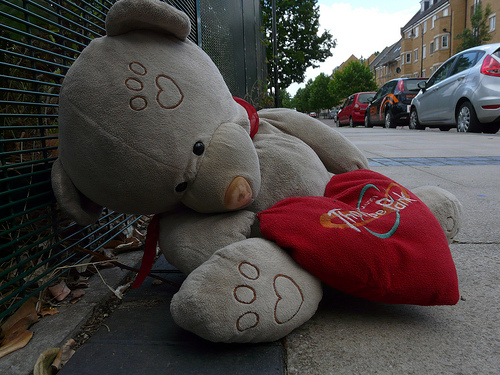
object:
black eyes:
[176, 139, 207, 195]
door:
[3, 0, 145, 265]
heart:
[257, 168, 462, 305]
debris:
[0, 205, 150, 353]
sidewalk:
[0, 127, 499, 374]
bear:
[50, 0, 462, 342]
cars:
[332, 42, 499, 133]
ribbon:
[231, 93, 260, 139]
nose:
[222, 175, 253, 210]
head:
[49, 1, 259, 225]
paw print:
[126, 59, 181, 118]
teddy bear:
[50, 0, 462, 344]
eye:
[191, 138, 205, 155]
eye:
[176, 178, 188, 194]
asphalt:
[71, 303, 287, 373]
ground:
[2, 120, 498, 374]